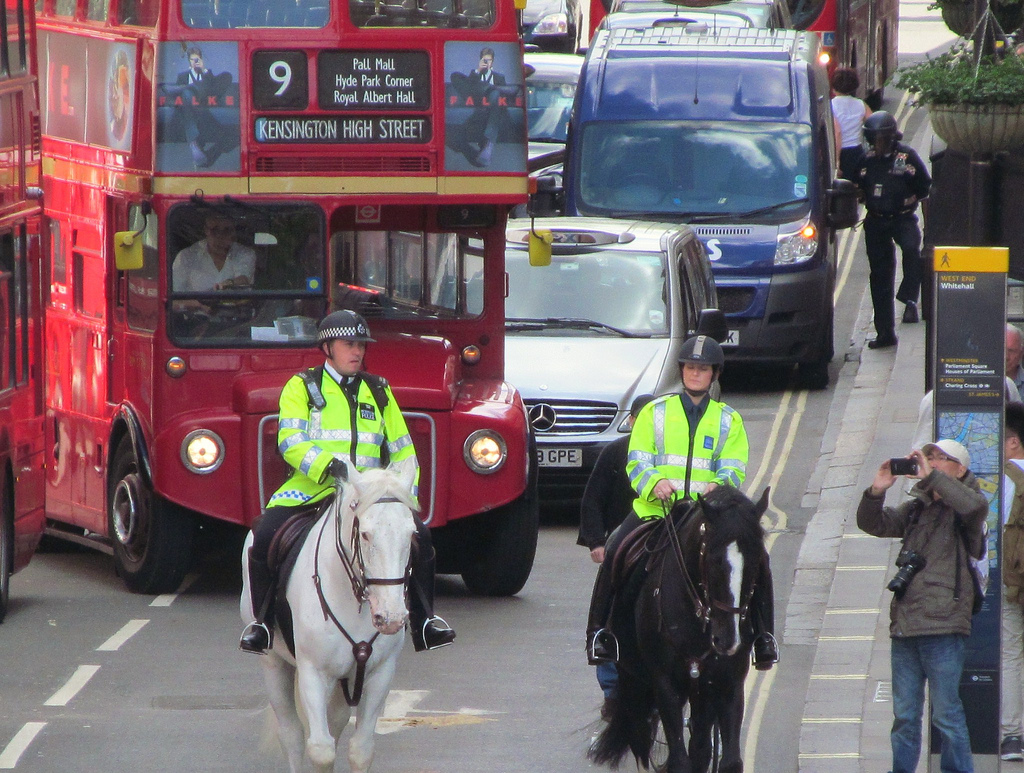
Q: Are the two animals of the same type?
A: Yes, all the animals are horses.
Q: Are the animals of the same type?
A: Yes, all the animals are horses.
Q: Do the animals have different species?
A: No, all the animals are horses.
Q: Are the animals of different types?
A: No, all the animals are horses.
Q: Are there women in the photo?
A: Yes, there is a woman.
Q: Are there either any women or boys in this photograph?
A: Yes, there is a woman.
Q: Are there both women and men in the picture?
A: Yes, there are both a woman and a man.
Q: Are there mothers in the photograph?
A: No, there are no mothers.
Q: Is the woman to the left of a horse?
A: No, the woman is to the right of a horse.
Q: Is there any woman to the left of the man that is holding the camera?
A: Yes, there is a woman to the left of the man.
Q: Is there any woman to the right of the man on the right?
A: No, the woman is to the left of the man.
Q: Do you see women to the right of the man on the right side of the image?
A: No, the woman is to the left of the man.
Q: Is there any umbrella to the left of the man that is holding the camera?
A: No, there is a woman to the left of the man.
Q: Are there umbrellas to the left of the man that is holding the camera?
A: No, there is a woman to the left of the man.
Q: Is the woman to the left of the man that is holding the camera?
A: Yes, the woman is to the left of the man.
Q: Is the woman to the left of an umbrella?
A: No, the woman is to the left of the man.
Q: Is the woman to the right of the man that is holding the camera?
A: No, the woman is to the left of the man.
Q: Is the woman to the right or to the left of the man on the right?
A: The woman is to the left of the man.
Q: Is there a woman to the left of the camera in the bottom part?
A: Yes, there is a woman to the left of the camera.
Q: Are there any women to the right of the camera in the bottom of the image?
A: No, the woman is to the left of the camera.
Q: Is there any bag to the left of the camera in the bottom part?
A: No, there is a woman to the left of the camera.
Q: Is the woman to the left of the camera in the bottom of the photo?
A: Yes, the woman is to the left of the camera.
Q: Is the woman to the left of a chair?
A: No, the woman is to the left of the camera.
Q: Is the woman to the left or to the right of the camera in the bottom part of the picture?
A: The woman is to the left of the camera.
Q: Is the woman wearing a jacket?
A: Yes, the woman is wearing a jacket.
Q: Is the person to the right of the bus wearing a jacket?
A: Yes, the woman is wearing a jacket.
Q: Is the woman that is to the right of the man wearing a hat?
A: No, the woman is wearing a jacket.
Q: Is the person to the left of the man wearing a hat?
A: No, the woman is wearing a jacket.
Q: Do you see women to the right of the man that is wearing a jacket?
A: Yes, there is a woman to the right of the man.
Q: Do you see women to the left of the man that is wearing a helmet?
A: No, the woman is to the right of the man.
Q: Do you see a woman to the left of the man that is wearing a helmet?
A: No, the woman is to the right of the man.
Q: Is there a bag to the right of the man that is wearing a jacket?
A: No, there is a woman to the right of the man.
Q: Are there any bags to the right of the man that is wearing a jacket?
A: No, there is a woman to the right of the man.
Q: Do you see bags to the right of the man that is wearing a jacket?
A: No, there is a woman to the right of the man.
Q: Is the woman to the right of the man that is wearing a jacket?
A: Yes, the woman is to the right of the man.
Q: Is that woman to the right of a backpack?
A: No, the woman is to the right of the man.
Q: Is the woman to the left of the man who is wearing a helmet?
A: No, the woman is to the right of the man.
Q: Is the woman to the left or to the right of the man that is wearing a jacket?
A: The woman is to the right of the man.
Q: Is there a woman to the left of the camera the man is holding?
A: Yes, there is a woman to the left of the camera.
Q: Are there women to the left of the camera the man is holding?
A: Yes, there is a woman to the left of the camera.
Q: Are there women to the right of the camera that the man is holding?
A: No, the woman is to the left of the camera.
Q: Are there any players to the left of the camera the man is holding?
A: No, there is a woman to the left of the camera.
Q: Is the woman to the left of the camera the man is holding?
A: Yes, the woman is to the left of the camera.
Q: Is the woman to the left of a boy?
A: No, the woman is to the left of the camera.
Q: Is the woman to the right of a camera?
A: No, the woman is to the left of a camera.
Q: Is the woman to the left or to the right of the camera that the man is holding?
A: The woman is to the left of the camera.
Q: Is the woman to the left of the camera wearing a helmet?
A: Yes, the woman is wearing a helmet.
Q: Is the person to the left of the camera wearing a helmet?
A: Yes, the woman is wearing a helmet.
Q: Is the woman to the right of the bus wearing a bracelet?
A: No, the woman is wearing a helmet.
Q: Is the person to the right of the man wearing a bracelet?
A: No, the woman is wearing a helmet.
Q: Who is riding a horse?
A: The woman is riding a horse.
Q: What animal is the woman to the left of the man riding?
A: The woman is riding a horse.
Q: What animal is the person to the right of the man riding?
A: The woman is riding a horse.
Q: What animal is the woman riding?
A: The woman is riding a horse.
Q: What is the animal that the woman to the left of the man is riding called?
A: The animal is a horse.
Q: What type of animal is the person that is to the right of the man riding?
A: The woman is riding a horse.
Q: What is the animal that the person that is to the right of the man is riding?
A: The animal is a horse.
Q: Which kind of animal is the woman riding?
A: The woman is riding a horse.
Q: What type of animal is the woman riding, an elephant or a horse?
A: The woman is riding a horse.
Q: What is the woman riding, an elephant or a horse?
A: The woman is riding a horse.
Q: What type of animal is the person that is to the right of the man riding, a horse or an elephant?
A: The woman is riding a horse.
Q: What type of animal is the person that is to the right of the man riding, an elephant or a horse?
A: The woman is riding a horse.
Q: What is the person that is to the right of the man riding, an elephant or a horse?
A: The woman is riding a horse.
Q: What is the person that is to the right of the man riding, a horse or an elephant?
A: The woman is riding a horse.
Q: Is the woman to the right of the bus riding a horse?
A: Yes, the woman is riding a horse.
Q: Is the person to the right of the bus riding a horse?
A: Yes, the woman is riding a horse.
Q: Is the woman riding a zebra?
A: No, the woman is riding a horse.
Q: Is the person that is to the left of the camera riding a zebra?
A: No, the woman is riding a horse.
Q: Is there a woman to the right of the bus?
A: Yes, there is a woman to the right of the bus.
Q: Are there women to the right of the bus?
A: Yes, there is a woman to the right of the bus.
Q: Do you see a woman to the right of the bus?
A: Yes, there is a woman to the right of the bus.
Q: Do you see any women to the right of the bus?
A: Yes, there is a woman to the right of the bus.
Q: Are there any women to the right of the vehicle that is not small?
A: Yes, there is a woman to the right of the bus.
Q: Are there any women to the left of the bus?
A: No, the woman is to the right of the bus.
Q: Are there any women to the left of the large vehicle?
A: No, the woman is to the right of the bus.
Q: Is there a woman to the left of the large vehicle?
A: No, the woman is to the right of the bus.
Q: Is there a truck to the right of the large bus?
A: No, there is a woman to the right of the bus.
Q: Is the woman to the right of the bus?
A: Yes, the woman is to the right of the bus.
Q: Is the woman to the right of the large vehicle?
A: Yes, the woman is to the right of the bus.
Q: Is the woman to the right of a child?
A: No, the woman is to the right of the bus.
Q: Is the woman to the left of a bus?
A: No, the woman is to the right of a bus.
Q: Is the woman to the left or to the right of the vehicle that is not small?
A: The woman is to the right of the bus.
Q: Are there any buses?
A: Yes, there is a bus.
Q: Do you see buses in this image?
A: Yes, there is a bus.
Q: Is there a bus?
A: Yes, there is a bus.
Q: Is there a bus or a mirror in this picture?
A: Yes, there is a bus.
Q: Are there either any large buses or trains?
A: Yes, there is a large bus.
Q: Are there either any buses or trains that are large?
A: Yes, the bus is large.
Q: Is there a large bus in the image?
A: Yes, there is a large bus.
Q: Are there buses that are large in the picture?
A: Yes, there is a large bus.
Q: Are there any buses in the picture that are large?
A: Yes, there is a bus that is large.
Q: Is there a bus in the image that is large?
A: Yes, there is a bus that is large.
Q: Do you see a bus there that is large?
A: Yes, there is a bus that is large.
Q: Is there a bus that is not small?
A: Yes, there is a large bus.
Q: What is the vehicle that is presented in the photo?
A: The vehicle is a bus.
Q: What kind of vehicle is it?
A: The vehicle is a bus.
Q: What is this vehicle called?
A: This is a bus.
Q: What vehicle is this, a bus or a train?
A: This is a bus.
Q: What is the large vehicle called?
A: The vehicle is a bus.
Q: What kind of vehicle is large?
A: The vehicle is a bus.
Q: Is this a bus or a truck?
A: This is a bus.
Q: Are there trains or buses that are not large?
A: No, there is a bus but it is large.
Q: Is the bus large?
A: Yes, the bus is large.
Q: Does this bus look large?
A: Yes, the bus is large.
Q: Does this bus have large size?
A: Yes, the bus is large.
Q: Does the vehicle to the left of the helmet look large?
A: Yes, the bus is large.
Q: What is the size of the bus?
A: The bus is large.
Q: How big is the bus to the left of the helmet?
A: The bus is large.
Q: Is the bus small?
A: No, the bus is large.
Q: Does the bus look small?
A: No, the bus is large.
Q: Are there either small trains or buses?
A: No, there is a bus but it is large.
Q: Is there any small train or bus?
A: No, there is a bus but it is large.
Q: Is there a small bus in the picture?
A: No, there is a bus but it is large.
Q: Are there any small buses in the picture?
A: No, there is a bus but it is large.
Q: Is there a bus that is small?
A: No, there is a bus but it is large.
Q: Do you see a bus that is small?
A: No, there is a bus but it is large.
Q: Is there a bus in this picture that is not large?
A: No, there is a bus but it is large.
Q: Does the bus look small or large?
A: The bus is large.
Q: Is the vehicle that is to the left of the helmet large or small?
A: The bus is large.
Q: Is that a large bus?
A: Yes, that is a large bus.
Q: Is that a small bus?
A: No, that is a large bus.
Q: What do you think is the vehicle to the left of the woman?
A: The vehicle is a bus.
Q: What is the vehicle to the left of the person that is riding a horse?
A: The vehicle is a bus.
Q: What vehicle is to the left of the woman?
A: The vehicle is a bus.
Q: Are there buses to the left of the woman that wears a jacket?
A: Yes, there is a bus to the left of the woman.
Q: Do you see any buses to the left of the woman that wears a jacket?
A: Yes, there is a bus to the left of the woman.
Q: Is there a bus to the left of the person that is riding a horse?
A: Yes, there is a bus to the left of the woman.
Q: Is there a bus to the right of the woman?
A: No, the bus is to the left of the woman.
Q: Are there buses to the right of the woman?
A: No, the bus is to the left of the woman.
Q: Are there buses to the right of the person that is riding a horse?
A: No, the bus is to the left of the woman.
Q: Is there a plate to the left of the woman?
A: No, there is a bus to the left of the woman.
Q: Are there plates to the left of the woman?
A: No, there is a bus to the left of the woman.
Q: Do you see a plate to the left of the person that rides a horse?
A: No, there is a bus to the left of the woman.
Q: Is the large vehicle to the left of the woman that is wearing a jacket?
A: Yes, the bus is to the left of the woman.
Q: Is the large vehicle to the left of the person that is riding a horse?
A: Yes, the bus is to the left of the woman.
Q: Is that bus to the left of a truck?
A: No, the bus is to the left of the woman.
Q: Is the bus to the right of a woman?
A: No, the bus is to the left of a woman.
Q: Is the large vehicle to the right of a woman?
A: No, the bus is to the left of a woman.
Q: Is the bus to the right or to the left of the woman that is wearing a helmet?
A: The bus is to the left of the woman.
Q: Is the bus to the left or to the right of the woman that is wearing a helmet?
A: The bus is to the left of the woman.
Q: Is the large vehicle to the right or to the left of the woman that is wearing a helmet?
A: The bus is to the left of the woman.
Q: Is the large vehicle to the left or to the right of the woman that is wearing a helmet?
A: The bus is to the left of the woman.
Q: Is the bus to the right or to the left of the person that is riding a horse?
A: The bus is to the left of the woman.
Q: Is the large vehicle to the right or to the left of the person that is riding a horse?
A: The bus is to the left of the woman.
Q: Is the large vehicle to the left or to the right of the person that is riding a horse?
A: The bus is to the left of the woman.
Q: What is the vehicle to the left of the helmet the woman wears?
A: The vehicle is a bus.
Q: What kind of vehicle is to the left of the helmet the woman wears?
A: The vehicle is a bus.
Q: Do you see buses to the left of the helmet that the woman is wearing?
A: Yes, there is a bus to the left of the helmet.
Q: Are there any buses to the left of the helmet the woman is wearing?
A: Yes, there is a bus to the left of the helmet.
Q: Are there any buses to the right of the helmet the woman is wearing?
A: No, the bus is to the left of the helmet.